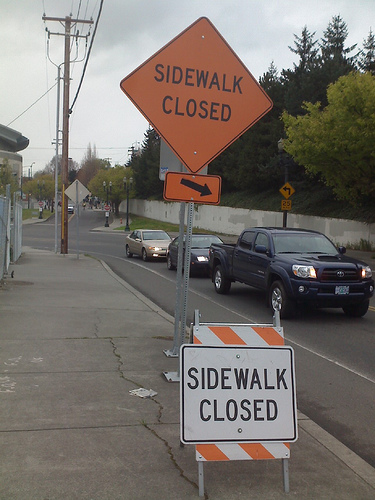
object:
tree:
[277, 66, 375, 212]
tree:
[355, 27, 375, 68]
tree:
[279, 16, 326, 174]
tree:
[246, 56, 280, 192]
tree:
[138, 119, 162, 193]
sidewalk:
[0, 248, 373, 499]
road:
[0, 206, 375, 473]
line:
[65, 247, 374, 385]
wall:
[118, 199, 375, 253]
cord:
[68, 0, 103, 115]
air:
[1, 1, 374, 119]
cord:
[69, 0, 90, 77]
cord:
[68, 0, 82, 53]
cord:
[69, 1, 74, 14]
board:
[62, 183, 65, 245]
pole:
[60, 18, 72, 256]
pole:
[54, 63, 60, 253]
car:
[207, 226, 375, 321]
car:
[166, 232, 226, 279]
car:
[125, 229, 173, 261]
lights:
[292, 262, 317, 282]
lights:
[361, 264, 374, 282]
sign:
[163, 170, 222, 205]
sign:
[119, 14, 274, 174]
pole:
[178, 200, 195, 352]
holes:
[191, 202, 193, 204]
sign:
[179, 342, 299, 445]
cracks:
[93, 312, 100, 338]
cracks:
[108, 335, 124, 371]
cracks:
[119, 371, 165, 423]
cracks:
[142, 425, 211, 498]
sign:
[279, 182, 295, 200]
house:
[0, 123, 29, 202]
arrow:
[180, 177, 212, 198]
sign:
[281, 199, 291, 210]